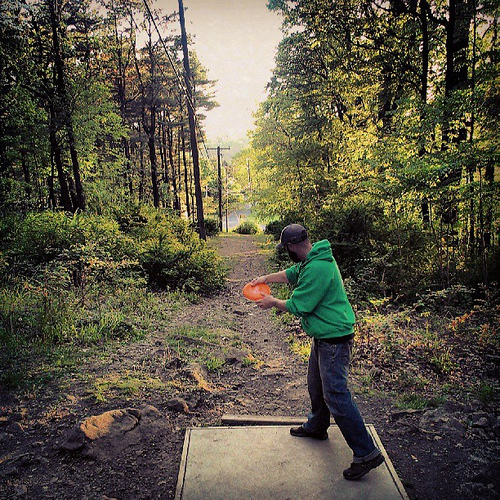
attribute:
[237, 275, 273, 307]
frisbee — orange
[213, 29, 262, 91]
sky — brown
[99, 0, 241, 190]
utility lines — overhead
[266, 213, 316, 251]
cap — orange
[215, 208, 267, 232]
water — green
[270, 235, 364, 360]
shirt — green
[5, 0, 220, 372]
woods — green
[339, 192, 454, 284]
vegetation — green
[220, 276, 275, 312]
frisbee — orange colored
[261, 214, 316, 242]
cap — black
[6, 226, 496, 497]
road — bare, dirt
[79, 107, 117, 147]
leaves — green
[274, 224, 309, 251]
cap — black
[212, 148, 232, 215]
pole — utility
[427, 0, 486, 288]
tree — green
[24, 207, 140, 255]
vegetation — green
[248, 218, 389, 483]
man — green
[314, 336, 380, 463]
leg — person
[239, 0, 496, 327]
trees — green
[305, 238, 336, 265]
hood — green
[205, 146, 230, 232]
pole — telephone communications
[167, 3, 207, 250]
pole — electricity 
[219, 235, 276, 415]
path — dirt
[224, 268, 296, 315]
freesbee — orange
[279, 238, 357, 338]
hoodie — green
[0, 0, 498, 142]
sky — bright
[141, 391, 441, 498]
platform — wooden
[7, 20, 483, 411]
forest — side